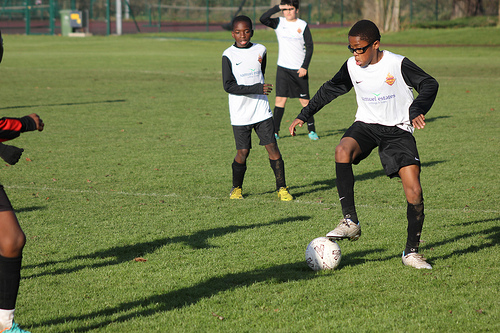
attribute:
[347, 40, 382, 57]
glasses — thin rimmed, black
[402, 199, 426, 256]
shinguards — black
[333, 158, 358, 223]
shinguards — black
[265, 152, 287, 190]
shinguards — black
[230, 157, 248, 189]
shinguards — black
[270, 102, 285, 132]
shinguards — black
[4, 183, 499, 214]
line — white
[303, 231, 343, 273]
ball — soccer, white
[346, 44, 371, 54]
glasses — black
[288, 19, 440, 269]
boy — playing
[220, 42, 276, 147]
uniform — white, black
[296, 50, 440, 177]
uniform — white, black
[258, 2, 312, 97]
uniform — white, black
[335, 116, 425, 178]
shorts — black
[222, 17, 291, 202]
boy — playing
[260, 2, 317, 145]
boy — playing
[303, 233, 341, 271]
ball — black, white, soccer ball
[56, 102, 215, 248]
soccer field — large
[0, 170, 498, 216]
white line — faded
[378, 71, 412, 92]
logo — small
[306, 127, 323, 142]
soccer cleat — light, blue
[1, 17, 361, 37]
walkway — dark, red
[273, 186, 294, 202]
shoe — yellow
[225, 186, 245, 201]
shoe — yellow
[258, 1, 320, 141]
kid — playing soccer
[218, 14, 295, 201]
kid — playing soccer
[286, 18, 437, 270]
kid — playing soccer